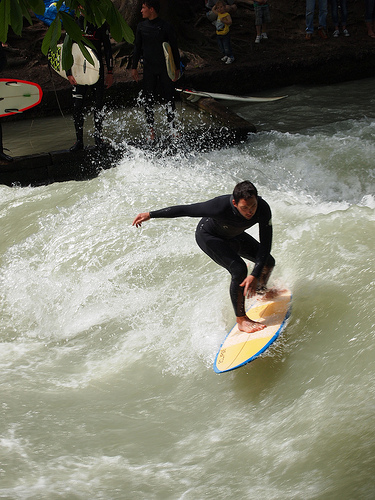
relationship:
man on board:
[135, 178, 284, 332] [217, 286, 295, 376]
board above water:
[217, 286, 295, 376] [0, 123, 367, 494]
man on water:
[135, 178, 284, 332] [0, 123, 367, 494]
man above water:
[135, 178, 284, 332] [0, 123, 367, 494]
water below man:
[0, 123, 367, 494] [135, 178, 284, 332]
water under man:
[0, 123, 367, 494] [135, 178, 284, 332]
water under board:
[0, 123, 367, 494] [217, 286, 295, 376]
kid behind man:
[210, 4, 240, 66] [135, 178, 284, 332]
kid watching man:
[210, 4, 240, 66] [135, 178, 284, 332]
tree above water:
[0, 0, 139, 75] [0, 123, 367, 494]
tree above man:
[0, 0, 139, 75] [135, 178, 284, 332]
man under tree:
[135, 178, 284, 332] [0, 0, 139, 75]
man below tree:
[135, 178, 284, 332] [0, 0, 139, 75]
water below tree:
[0, 123, 367, 494] [0, 0, 139, 75]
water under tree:
[0, 123, 367, 494] [0, 0, 139, 75]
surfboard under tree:
[35, 40, 106, 101] [0, 0, 139, 75]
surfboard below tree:
[35, 40, 106, 101] [0, 0, 139, 75]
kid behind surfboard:
[210, 4, 240, 66] [35, 40, 106, 101]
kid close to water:
[210, 4, 240, 66] [0, 123, 367, 494]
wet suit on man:
[153, 197, 273, 304] [135, 178, 284, 332]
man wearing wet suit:
[135, 178, 284, 332] [153, 197, 273, 304]